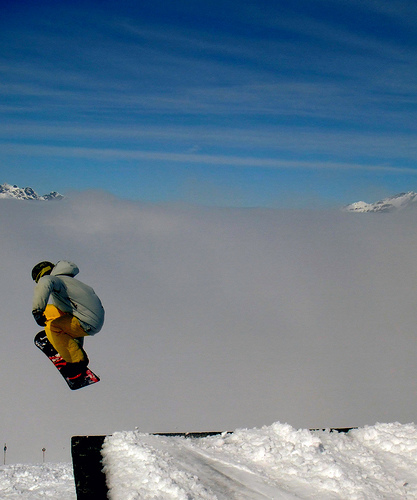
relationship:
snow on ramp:
[101, 423, 416, 497] [68, 423, 416, 499]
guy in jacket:
[30, 256, 107, 379] [28, 259, 108, 339]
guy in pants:
[30, 256, 107, 379] [36, 304, 91, 367]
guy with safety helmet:
[30, 256, 107, 379] [28, 259, 55, 282]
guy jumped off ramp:
[30, 256, 107, 379] [68, 423, 416, 499]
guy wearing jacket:
[30, 256, 107, 379] [28, 259, 108, 339]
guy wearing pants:
[30, 256, 107, 379] [36, 304, 91, 367]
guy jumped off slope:
[30, 256, 107, 379] [67, 415, 415, 499]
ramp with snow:
[68, 423, 416, 499] [101, 423, 416, 497]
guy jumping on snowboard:
[30, 256, 107, 379] [31, 326, 102, 395]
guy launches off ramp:
[30, 256, 107, 379] [68, 423, 416, 499]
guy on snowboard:
[30, 256, 107, 379] [31, 326, 102, 395]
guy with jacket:
[30, 256, 107, 379] [28, 259, 108, 339]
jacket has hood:
[28, 259, 108, 339] [50, 258, 79, 277]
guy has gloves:
[30, 256, 107, 379] [29, 303, 52, 330]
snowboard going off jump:
[31, 326, 102, 395] [69, 419, 416, 498]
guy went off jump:
[30, 256, 107, 379] [69, 419, 416, 498]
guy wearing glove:
[30, 256, 107, 379] [32, 303, 48, 328]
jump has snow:
[69, 419, 416, 498] [101, 423, 416, 497]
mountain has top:
[342, 184, 413, 214] [342, 187, 415, 215]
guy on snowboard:
[25, 256, 107, 379] [31, 326, 102, 395]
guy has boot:
[25, 256, 107, 379] [55, 352, 91, 380]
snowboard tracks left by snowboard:
[149, 425, 348, 499] [31, 326, 102, 395]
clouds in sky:
[255, 24, 413, 184] [0, 1, 413, 202]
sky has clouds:
[0, 1, 413, 202] [255, 24, 413, 184]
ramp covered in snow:
[68, 423, 416, 499] [101, 423, 416, 497]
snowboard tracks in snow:
[149, 425, 415, 499] [101, 423, 416, 497]